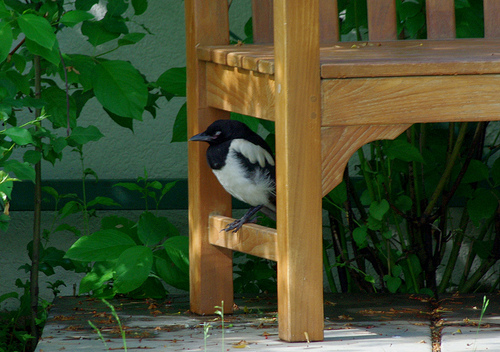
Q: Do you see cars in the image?
A: No, there are no cars.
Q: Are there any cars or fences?
A: No, there are no cars or fences.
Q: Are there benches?
A: Yes, there is a bench.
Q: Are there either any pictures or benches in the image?
A: Yes, there is a bench.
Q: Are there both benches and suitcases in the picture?
A: No, there is a bench but no suitcases.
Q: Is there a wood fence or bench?
A: Yes, there is a wood bench.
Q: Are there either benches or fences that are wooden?
A: Yes, the bench is wooden.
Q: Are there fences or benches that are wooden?
A: Yes, the bench is wooden.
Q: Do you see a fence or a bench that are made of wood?
A: Yes, the bench is made of wood.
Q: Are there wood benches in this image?
A: Yes, there is a wood bench.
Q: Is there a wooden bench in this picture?
A: Yes, there is a wood bench.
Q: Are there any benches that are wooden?
A: Yes, there is a bench that is wooden.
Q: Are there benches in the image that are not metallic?
A: Yes, there is a wooden bench.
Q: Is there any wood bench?
A: Yes, there is a bench that is made of wood.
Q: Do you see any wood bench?
A: Yes, there is a bench that is made of wood.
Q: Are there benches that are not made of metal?
A: Yes, there is a bench that is made of wood.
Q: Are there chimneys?
A: No, there are no chimneys.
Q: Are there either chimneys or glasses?
A: No, there are no chimneys or glasses.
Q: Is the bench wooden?
A: Yes, the bench is wooden.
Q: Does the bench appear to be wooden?
A: Yes, the bench is wooden.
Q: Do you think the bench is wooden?
A: Yes, the bench is wooden.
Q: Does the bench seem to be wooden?
A: Yes, the bench is wooden.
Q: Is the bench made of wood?
A: Yes, the bench is made of wood.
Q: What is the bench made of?
A: The bench is made of wood.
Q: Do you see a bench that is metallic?
A: No, there is a bench but it is wooden.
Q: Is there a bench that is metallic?
A: No, there is a bench but it is wooden.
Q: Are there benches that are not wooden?
A: No, there is a bench but it is wooden.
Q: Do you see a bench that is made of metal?
A: No, there is a bench but it is made of wood.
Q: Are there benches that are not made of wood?
A: No, there is a bench but it is made of wood.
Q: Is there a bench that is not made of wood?
A: No, there is a bench but it is made of wood.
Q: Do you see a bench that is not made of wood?
A: No, there is a bench but it is made of wood.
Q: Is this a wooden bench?
A: Yes, this is a wooden bench.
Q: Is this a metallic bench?
A: No, this is a wooden bench.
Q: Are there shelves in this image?
A: No, there are no shelves.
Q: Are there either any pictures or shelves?
A: No, there are no shelves or pictures.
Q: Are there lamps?
A: No, there are no lamps.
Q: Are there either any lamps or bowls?
A: No, there are no lamps or bowls.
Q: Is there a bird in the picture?
A: Yes, there is a bird.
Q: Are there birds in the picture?
A: Yes, there is a bird.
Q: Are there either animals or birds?
A: Yes, there is a bird.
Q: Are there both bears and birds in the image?
A: No, there is a bird but no bears.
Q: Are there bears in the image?
A: No, there are no bears.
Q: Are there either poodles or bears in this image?
A: No, there are no bears or poodles.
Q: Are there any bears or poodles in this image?
A: No, there are no bears or poodles.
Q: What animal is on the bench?
A: The bird is on the bench.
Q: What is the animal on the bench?
A: The animal is a bird.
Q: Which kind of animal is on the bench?
A: The animal is a bird.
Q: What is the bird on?
A: The bird is on the bench.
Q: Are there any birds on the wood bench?
A: Yes, there is a bird on the bench.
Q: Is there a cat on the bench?
A: No, there is a bird on the bench.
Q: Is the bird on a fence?
A: No, the bird is on the bench.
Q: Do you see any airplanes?
A: No, there are no airplanes.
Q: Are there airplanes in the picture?
A: No, there are no airplanes.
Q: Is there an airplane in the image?
A: No, there are no airplanes.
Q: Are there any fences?
A: No, there are no fences.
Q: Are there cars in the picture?
A: No, there are no cars.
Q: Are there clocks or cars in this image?
A: No, there are no cars or clocks.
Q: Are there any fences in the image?
A: No, there are no fences.